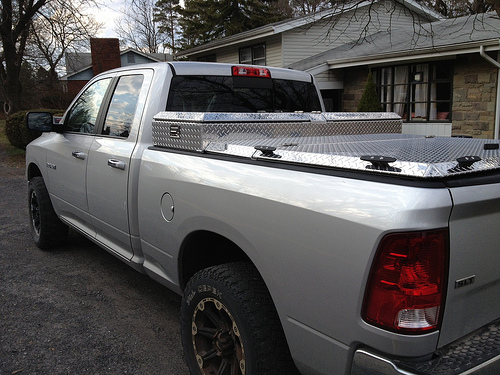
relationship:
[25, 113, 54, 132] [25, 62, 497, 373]
sideview mirror on side of pickup truck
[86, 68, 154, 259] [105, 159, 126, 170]
door has handle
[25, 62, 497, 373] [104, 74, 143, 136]
pickup truck has window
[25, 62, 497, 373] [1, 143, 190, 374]
pickup truck on top of driveway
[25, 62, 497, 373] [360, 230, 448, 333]
pickup truck has brakelight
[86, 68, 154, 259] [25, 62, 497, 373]
door on side of pickup truck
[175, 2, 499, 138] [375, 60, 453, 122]
house has window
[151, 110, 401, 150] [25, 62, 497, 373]
tool box on top of pickup truck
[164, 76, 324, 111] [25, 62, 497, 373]
back window on back of pickup truck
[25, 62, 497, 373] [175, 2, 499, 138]
pickup truck in front of house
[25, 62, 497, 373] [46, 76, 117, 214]
pickup truck has door